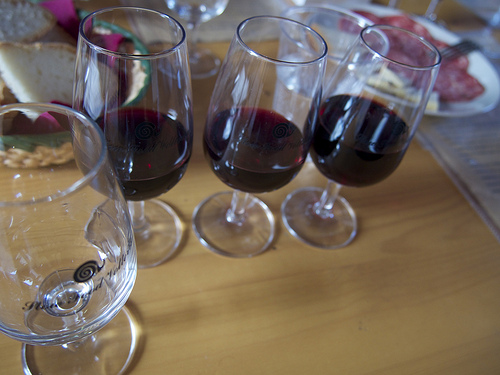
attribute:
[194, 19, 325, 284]
glass — wine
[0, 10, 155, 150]
trim — green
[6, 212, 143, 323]
writing — black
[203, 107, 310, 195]
wine — red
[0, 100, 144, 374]
glass — empty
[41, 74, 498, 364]
table — wood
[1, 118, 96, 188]
basket — brown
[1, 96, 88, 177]
basket — brown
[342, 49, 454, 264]
glass — wine